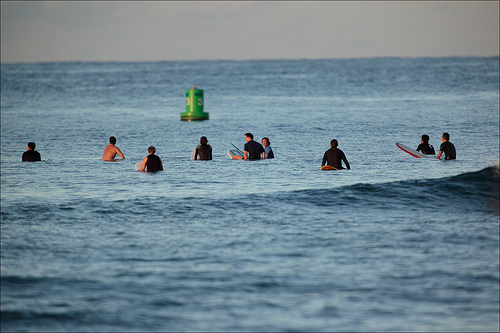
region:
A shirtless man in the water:
[100, 135, 126, 166]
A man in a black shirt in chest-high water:
[19, 139, 44, 164]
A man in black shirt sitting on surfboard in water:
[226, 131, 263, 163]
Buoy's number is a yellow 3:
[177, 83, 212, 124]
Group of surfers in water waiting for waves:
[16, 127, 472, 176]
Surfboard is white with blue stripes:
[225, 141, 252, 163]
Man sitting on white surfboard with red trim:
[392, 133, 462, 161]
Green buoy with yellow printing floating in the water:
[163, 73, 218, 126]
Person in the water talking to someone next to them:
[249, 130, 277, 162]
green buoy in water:
[175, 85, 212, 125]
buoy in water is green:
[176, 83, 211, 124]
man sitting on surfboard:
[433, 127, 457, 162]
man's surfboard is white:
[396, 140, 436, 160]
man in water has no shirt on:
[98, 134, 129, 163]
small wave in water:
[347, 160, 499, 205]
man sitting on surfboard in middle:
[228, 130, 267, 162]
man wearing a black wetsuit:
[316, 146, 351, 173]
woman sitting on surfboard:
[258, 135, 275, 158]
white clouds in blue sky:
[30, 15, 105, 47]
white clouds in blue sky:
[378, 2, 435, 37]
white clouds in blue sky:
[144, 3, 218, 34]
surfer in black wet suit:
[318, 129, 352, 170]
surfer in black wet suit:
[128, 141, 165, 166]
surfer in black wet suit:
[24, 126, 51, 168]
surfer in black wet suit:
[238, 125, 273, 173]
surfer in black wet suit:
[402, 119, 460, 170]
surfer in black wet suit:
[438, 113, 455, 165]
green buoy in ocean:
[180, 86, 214, 124]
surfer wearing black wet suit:
[320, 134, 349, 180]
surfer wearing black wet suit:
[440, 126, 462, 159]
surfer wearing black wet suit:
[139, 137, 163, 177]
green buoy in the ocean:
[172, 82, 214, 130]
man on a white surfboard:
[386, 129, 434, 163]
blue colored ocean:
[9, 59, 499, 331]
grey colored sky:
[3, 4, 498, 62]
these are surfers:
[36, 84, 404, 280]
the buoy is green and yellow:
[146, 63, 247, 140]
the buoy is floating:
[124, 60, 218, 124]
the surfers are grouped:
[66, 105, 391, 200]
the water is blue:
[113, 178, 292, 317]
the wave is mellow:
[111, 172, 389, 291]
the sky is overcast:
[152, 0, 278, 48]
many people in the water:
[1, 50, 478, 242]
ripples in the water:
[160, 208, 289, 259]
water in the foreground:
[150, 202, 365, 314]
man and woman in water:
[210, 112, 294, 192]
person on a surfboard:
[292, 120, 366, 197]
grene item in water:
[171, 75, 227, 125]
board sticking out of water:
[388, 129, 428, 167]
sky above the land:
[158, 8, 254, 43]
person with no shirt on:
[83, 123, 132, 174]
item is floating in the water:
[180, 87, 210, 120]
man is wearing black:
[23, 140, 41, 164]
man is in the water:
[21, 140, 41, 160]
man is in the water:
[100, 135, 120, 161]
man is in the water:
[136, 145, 161, 170]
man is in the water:
[193, 135, 214, 162]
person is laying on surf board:
[231, 132, 265, 162]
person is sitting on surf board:
[321, 137, 349, 172]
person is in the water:
[434, 132, 456, 159]